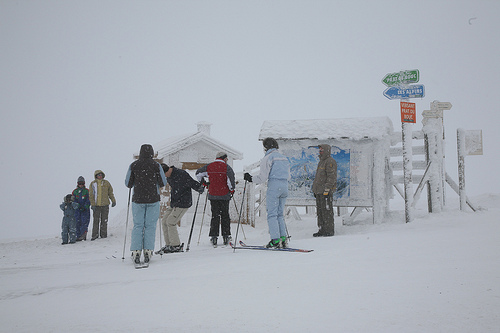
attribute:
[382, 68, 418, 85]
sign — green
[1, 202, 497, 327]
snow — white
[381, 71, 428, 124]
signs — one directional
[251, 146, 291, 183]
jacket — light blue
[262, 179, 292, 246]
pants — blue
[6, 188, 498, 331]
snow — lots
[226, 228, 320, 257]
skis — pair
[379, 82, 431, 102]
sign — blue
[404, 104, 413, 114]
lettering — white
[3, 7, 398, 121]
sky — gray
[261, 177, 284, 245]
pant — light blue